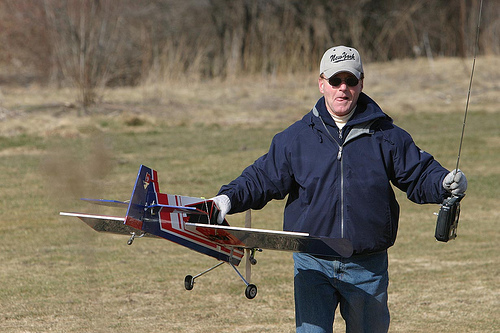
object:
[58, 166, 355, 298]
airplane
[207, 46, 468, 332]
man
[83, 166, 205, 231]
tail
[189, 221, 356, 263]
wing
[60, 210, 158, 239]
wing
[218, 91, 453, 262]
jacket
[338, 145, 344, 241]
zipper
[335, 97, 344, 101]
tongue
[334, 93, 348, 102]
mouth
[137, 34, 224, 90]
plants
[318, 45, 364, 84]
hat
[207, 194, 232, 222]
hand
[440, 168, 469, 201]
hand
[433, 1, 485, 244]
remote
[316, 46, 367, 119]
head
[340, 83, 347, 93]
nose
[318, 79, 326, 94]
ear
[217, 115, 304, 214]
arm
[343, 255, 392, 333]
leg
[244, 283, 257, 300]
wheel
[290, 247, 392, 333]
jeans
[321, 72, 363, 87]
sunglasses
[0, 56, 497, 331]
field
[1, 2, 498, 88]
bushes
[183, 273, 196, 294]
wheel